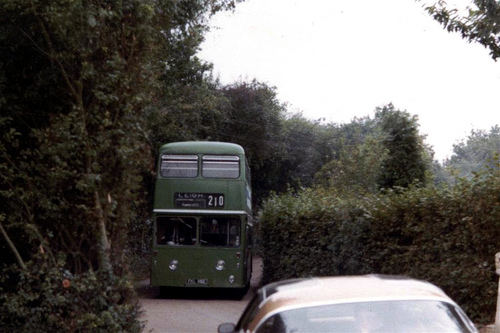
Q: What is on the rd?
A: Green bus 2.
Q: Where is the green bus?
A: On the rd.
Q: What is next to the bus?
A: Green hesges.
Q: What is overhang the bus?
A: Green trees.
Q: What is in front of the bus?
A: Car.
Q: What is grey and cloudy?
A: The sky.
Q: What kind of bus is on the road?
A: Double-decker.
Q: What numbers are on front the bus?
A: 2 and 0.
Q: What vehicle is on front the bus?
A: Small car.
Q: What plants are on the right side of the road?
A: Green bushes.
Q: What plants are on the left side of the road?
A: Green trees.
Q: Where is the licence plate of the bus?
A: On the bumper.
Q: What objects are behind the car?
A: Green bushes.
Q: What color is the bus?
A: Green.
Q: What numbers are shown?
A: 210.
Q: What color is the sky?
A: White.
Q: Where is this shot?
A: Road.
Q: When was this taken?
A: Daytime.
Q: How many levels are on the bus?
A: 2.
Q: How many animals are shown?
A: 0.